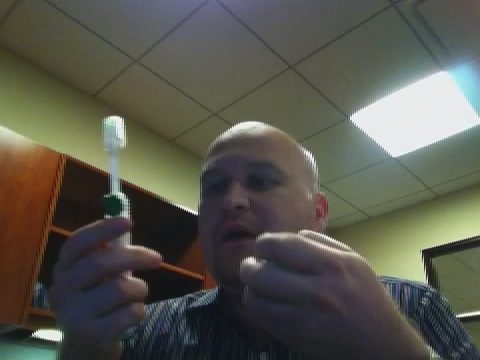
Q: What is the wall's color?
A: Is green.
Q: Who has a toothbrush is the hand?
A: A man.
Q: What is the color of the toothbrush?
A: Green and white.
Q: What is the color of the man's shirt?
A: Blue.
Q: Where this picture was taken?
A: In a room.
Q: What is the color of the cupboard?
A: Is brown.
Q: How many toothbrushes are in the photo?
A: One.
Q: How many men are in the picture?
A: One.